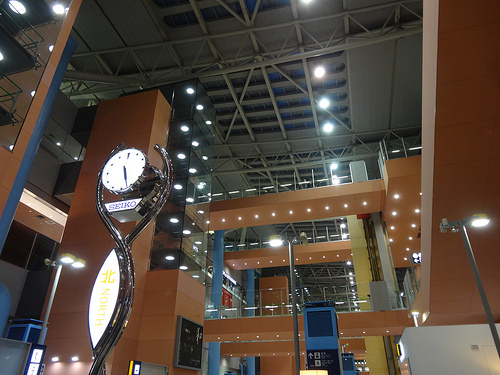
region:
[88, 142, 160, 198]
The clock is white.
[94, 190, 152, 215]
Seiko on a sign.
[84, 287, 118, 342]
North on a sign.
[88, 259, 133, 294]
Logo on the sign.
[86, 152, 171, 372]
The statue is curved.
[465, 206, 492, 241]
Light on a pole.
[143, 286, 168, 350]
The walls are brown.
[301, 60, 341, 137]
Lights on the ceiling.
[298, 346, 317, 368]
An arrow pointing up.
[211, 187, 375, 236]
Lights on the bottom of the catwalk.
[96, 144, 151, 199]
Black and white clock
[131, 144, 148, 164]
Black dots on clocks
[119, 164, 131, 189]
Hands on the clock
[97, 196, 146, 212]
Sign says Seiko under clock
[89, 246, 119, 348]
Chinese design and sign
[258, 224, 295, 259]
Light on the second floor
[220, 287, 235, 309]
Double red doors on second floor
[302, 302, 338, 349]
Top of info stand is blue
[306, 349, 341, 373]
Directions to some destinations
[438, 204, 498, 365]
Silver light pole on first floor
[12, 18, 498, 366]
Photo was taken inside a building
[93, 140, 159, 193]
A clock is in the foreground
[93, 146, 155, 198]
The clock is white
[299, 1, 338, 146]
Ceiling lights are on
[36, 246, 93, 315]
Lights are on a pole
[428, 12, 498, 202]
Part of the building is brown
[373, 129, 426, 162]
A fence is on the top floor of the building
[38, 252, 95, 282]
two lights are on the pole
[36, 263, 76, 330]
The pole is silver in color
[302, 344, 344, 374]
A dark blue directional sign in the background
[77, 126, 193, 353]
a stylized fancy clock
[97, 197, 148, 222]
the logo for seiko watches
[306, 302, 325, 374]
a directory kiosk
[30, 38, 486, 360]
a large modern shopping mall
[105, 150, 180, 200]
a clock at 5:27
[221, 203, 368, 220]
a row of recessed lights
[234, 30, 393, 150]
some skylights in the ceiling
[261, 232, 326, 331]
a lightpost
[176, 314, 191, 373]
an advertisement poster on the wall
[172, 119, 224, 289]
glass enclosed observatory decks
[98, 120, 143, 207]
white clock on pole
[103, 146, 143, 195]
time denoted by black dots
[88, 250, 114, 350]
yellow writing on black pole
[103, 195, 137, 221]
name brand under clock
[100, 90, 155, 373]
walls of room are tan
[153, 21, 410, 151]
ceiling of room is grey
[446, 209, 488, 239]
white light on right side of room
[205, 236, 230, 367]
blue metal beams in room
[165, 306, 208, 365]
black picture on wall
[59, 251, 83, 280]
white lights behind clock